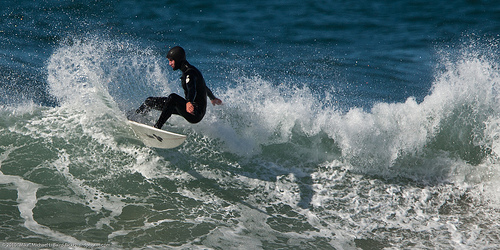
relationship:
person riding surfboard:
[120, 42, 240, 150] [102, 115, 188, 152]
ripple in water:
[289, 16, 494, 45] [7, 0, 498, 248]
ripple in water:
[169, 42, 291, 71] [7, 0, 498, 248]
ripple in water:
[70, 14, 252, 56] [7, 0, 498, 248]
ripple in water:
[1, 9, 242, 31] [7, 0, 498, 248]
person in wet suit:
[120, 42, 240, 150] [130, 48, 240, 140]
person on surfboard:
[120, 42, 240, 150] [125, 121, 170, 153]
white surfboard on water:
[123, 117, 188, 148] [7, 0, 498, 248]